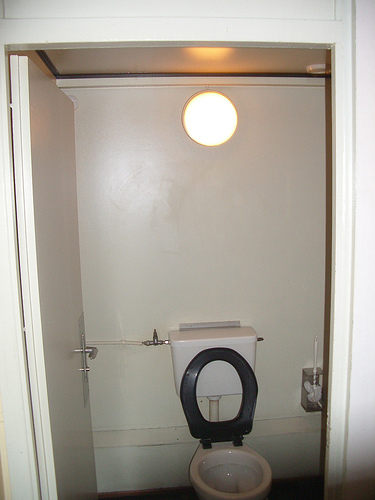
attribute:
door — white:
[9, 53, 103, 494]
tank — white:
[167, 320, 261, 399]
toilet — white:
[163, 321, 275, 494]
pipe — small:
[88, 335, 161, 351]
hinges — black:
[198, 436, 249, 448]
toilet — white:
[189, 445, 278, 497]